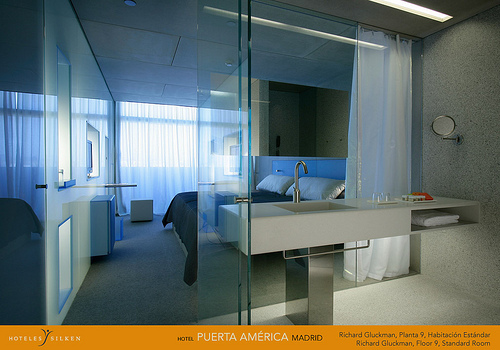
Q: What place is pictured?
A: It is a hotel room.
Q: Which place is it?
A: It is a hotel room.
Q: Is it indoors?
A: Yes, it is indoors.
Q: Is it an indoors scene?
A: Yes, it is indoors.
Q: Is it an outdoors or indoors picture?
A: It is indoors.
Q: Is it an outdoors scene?
A: No, it is indoors.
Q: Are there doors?
A: Yes, there is a door.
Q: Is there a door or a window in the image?
A: Yes, there is a door.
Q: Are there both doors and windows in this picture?
A: Yes, there are both a door and windows.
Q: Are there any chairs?
A: No, there are no chairs.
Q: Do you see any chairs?
A: No, there are no chairs.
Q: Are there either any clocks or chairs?
A: No, there are no chairs or clocks.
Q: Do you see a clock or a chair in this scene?
A: No, there are no chairs or clocks.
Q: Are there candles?
A: No, there are no candles.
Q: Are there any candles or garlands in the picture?
A: No, there are no candles or garlands.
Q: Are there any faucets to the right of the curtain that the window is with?
A: Yes, there is a faucet to the right of the curtain.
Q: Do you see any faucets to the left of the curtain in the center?
A: No, the faucet is to the right of the curtain.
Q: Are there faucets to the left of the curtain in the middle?
A: No, the faucet is to the right of the curtain.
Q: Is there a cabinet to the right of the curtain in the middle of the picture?
A: No, there is a faucet to the right of the curtain.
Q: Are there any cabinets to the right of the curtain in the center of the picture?
A: No, there is a faucet to the right of the curtain.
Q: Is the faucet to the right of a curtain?
A: Yes, the faucet is to the right of a curtain.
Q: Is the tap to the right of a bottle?
A: No, the tap is to the right of a curtain.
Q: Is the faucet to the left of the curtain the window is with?
A: No, the faucet is to the right of the curtain.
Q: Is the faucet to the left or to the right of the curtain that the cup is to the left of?
A: The faucet is to the right of the curtain.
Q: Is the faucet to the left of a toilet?
A: No, the faucet is to the left of the curtain.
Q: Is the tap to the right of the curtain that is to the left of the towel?
A: No, the tap is to the left of the curtain.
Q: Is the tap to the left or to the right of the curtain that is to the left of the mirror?
A: The tap is to the left of the curtain.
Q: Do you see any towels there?
A: Yes, there is a towel.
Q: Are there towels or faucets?
A: Yes, there is a towel.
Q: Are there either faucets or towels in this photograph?
A: Yes, there is a towel.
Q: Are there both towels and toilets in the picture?
A: No, there is a towel but no toilets.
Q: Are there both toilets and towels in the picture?
A: No, there is a towel but no toilets.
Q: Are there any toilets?
A: No, there are no toilets.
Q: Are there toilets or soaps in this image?
A: No, there are no toilets or soaps.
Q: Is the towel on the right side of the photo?
A: Yes, the towel is on the right of the image.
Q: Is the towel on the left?
A: No, the towel is on the right of the image.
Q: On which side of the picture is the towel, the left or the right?
A: The towel is on the right of the image.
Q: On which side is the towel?
A: The towel is on the right of the image.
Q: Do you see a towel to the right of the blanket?
A: Yes, there is a towel to the right of the blanket.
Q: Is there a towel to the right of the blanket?
A: Yes, there is a towel to the right of the blanket.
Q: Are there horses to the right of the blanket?
A: No, there is a towel to the right of the blanket.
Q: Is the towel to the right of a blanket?
A: Yes, the towel is to the right of a blanket.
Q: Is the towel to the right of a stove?
A: No, the towel is to the right of a blanket.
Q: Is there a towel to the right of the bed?
A: Yes, there is a towel to the right of the bed.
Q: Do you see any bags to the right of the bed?
A: No, there is a towel to the right of the bed.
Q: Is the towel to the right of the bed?
A: Yes, the towel is to the right of the bed.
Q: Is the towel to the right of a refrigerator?
A: No, the towel is to the right of the bed.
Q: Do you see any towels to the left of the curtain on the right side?
A: No, the towel is to the right of the curtain.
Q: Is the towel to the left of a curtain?
A: No, the towel is to the right of a curtain.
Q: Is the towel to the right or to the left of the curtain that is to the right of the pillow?
A: The towel is to the right of the curtain.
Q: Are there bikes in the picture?
A: No, there are no bikes.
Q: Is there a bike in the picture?
A: No, there are no bikes.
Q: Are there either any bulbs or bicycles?
A: No, there are no bicycles or bulbs.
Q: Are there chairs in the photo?
A: No, there are no chairs.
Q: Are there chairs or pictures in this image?
A: No, there are no chairs or pictures.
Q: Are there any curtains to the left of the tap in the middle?
A: Yes, there is a curtain to the left of the faucet.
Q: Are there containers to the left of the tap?
A: No, there is a curtain to the left of the tap.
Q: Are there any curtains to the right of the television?
A: Yes, there is a curtain to the right of the television.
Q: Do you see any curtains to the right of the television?
A: Yes, there is a curtain to the right of the television.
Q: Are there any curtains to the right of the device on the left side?
A: Yes, there is a curtain to the right of the television.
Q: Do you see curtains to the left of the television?
A: No, the curtain is to the right of the television.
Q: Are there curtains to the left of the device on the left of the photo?
A: No, the curtain is to the right of the television.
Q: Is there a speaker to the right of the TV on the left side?
A: No, there is a curtain to the right of the television.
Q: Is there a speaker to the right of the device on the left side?
A: No, there is a curtain to the right of the television.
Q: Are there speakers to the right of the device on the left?
A: No, there is a curtain to the right of the television.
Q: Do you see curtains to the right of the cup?
A: Yes, there is a curtain to the right of the cup.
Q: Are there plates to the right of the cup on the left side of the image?
A: No, there is a curtain to the right of the cup.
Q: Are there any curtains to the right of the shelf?
A: Yes, there is a curtain to the right of the shelf.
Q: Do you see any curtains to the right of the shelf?
A: Yes, there is a curtain to the right of the shelf.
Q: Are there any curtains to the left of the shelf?
A: No, the curtain is to the right of the shelf.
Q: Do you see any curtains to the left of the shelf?
A: No, the curtain is to the right of the shelf.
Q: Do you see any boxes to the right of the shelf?
A: No, there is a curtain to the right of the shelf.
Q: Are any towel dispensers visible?
A: No, there are no towel dispensers.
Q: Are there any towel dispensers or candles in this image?
A: No, there are no towel dispensers or candles.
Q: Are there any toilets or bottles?
A: No, there are no toilets or bottles.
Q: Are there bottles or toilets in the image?
A: No, there are no toilets or bottles.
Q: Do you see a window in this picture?
A: Yes, there is a window.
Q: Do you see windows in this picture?
A: Yes, there is a window.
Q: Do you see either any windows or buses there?
A: Yes, there is a window.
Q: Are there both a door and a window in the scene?
A: Yes, there are both a window and a door.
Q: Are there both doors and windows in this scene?
A: Yes, there are both a window and doors.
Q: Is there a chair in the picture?
A: No, there are no chairs.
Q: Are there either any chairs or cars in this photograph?
A: No, there are no chairs or cars.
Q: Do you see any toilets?
A: No, there are no toilets.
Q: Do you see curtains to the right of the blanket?
A: Yes, there is a curtain to the right of the blanket.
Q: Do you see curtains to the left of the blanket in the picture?
A: No, the curtain is to the right of the blanket.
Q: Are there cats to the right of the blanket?
A: No, there is a curtain to the right of the blanket.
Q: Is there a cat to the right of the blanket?
A: No, there is a curtain to the right of the blanket.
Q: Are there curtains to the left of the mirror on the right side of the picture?
A: Yes, there is a curtain to the left of the mirror.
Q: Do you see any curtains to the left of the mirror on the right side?
A: Yes, there is a curtain to the left of the mirror.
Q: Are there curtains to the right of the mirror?
A: No, the curtain is to the left of the mirror.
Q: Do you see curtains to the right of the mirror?
A: No, the curtain is to the left of the mirror.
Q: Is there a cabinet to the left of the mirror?
A: No, there is a curtain to the left of the mirror.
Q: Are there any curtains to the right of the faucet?
A: Yes, there is a curtain to the right of the faucet.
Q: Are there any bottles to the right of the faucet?
A: No, there is a curtain to the right of the faucet.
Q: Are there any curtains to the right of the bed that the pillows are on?
A: Yes, there is a curtain to the right of the bed.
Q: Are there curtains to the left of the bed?
A: No, the curtain is to the right of the bed.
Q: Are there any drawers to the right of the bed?
A: No, there is a curtain to the right of the bed.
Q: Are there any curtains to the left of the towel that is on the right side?
A: Yes, there is a curtain to the left of the towel.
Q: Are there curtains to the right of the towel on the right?
A: No, the curtain is to the left of the towel.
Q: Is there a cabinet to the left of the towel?
A: No, there is a curtain to the left of the towel.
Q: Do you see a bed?
A: Yes, there is a bed.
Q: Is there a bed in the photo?
A: Yes, there is a bed.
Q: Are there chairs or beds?
A: Yes, there is a bed.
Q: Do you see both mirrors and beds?
A: Yes, there are both a bed and a mirror.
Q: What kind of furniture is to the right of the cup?
A: The piece of furniture is a bed.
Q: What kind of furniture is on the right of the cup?
A: The piece of furniture is a bed.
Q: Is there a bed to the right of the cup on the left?
A: Yes, there is a bed to the right of the cup.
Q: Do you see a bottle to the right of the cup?
A: No, there is a bed to the right of the cup.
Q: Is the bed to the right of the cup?
A: Yes, the bed is to the right of the cup.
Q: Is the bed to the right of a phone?
A: No, the bed is to the right of the cup.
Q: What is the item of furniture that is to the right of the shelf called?
A: The piece of furniture is a bed.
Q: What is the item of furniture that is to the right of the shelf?
A: The piece of furniture is a bed.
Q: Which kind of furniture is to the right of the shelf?
A: The piece of furniture is a bed.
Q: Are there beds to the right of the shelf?
A: Yes, there is a bed to the right of the shelf.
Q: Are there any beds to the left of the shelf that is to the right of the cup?
A: No, the bed is to the right of the shelf.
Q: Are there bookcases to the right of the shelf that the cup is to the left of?
A: No, there is a bed to the right of the shelf.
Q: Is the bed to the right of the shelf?
A: Yes, the bed is to the right of the shelf.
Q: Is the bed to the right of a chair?
A: No, the bed is to the right of the shelf.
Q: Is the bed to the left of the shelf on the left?
A: No, the bed is to the right of the shelf.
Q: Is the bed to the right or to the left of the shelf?
A: The bed is to the right of the shelf.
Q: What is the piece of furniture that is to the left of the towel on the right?
A: The piece of furniture is a bed.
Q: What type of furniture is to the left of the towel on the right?
A: The piece of furniture is a bed.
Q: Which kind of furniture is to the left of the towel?
A: The piece of furniture is a bed.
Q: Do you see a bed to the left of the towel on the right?
A: Yes, there is a bed to the left of the towel.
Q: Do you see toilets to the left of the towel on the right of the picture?
A: No, there is a bed to the left of the towel.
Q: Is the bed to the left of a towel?
A: Yes, the bed is to the left of a towel.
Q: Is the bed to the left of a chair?
A: No, the bed is to the left of a towel.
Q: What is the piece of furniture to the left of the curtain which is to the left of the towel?
A: The piece of furniture is a bed.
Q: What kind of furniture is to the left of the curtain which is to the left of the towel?
A: The piece of furniture is a bed.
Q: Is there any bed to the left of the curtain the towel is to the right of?
A: Yes, there is a bed to the left of the curtain.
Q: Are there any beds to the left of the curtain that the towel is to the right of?
A: Yes, there is a bed to the left of the curtain.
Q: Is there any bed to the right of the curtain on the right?
A: No, the bed is to the left of the curtain.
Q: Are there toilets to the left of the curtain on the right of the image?
A: No, there is a bed to the left of the curtain.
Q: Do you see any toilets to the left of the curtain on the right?
A: No, there is a bed to the left of the curtain.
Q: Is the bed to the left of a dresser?
A: No, the bed is to the left of the curtain.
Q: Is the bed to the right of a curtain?
A: No, the bed is to the left of a curtain.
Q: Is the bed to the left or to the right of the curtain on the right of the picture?
A: The bed is to the left of the curtain.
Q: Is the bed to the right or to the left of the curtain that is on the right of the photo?
A: The bed is to the left of the curtain.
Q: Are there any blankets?
A: Yes, there is a blanket.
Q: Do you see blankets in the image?
A: Yes, there is a blanket.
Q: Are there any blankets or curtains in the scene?
A: Yes, there is a blanket.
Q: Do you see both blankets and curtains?
A: Yes, there are both a blanket and curtains.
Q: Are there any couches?
A: No, there are no couches.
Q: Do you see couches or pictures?
A: No, there are no couches or pictures.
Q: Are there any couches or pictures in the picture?
A: No, there are no couches or pictures.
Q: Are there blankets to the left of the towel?
A: Yes, there is a blanket to the left of the towel.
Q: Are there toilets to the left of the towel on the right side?
A: No, there is a blanket to the left of the towel.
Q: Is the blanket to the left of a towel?
A: Yes, the blanket is to the left of a towel.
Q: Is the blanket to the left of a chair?
A: No, the blanket is to the left of a towel.